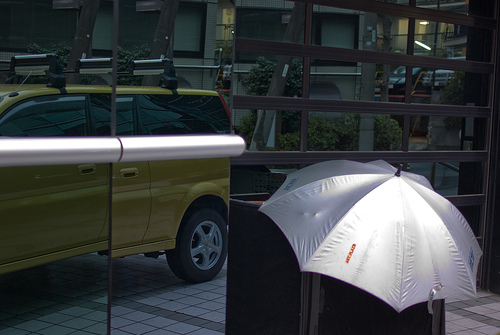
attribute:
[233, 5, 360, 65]
window — rectangular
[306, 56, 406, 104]
window — rectangular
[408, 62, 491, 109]
window — rectangular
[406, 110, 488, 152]
window — rectangular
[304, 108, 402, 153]
window — rectangular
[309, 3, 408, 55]
window — rectangular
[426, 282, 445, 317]
strap — small, grey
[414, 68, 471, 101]
window — rectangular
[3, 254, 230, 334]
tiles — grey , cement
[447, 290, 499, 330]
tiles — grey , cement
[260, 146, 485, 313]
umbrella — white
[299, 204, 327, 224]
bump — small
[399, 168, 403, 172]
black — small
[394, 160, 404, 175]
cap — small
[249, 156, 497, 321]
umbrella — white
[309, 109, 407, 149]
window — rectangular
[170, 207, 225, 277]
tire —  large,  black,  vehicle's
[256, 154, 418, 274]
umbrella — opened, white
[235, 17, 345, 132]
tree — small green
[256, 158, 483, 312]
umbrella — white, open, shiny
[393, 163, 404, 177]
top — pointed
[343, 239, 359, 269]
label — red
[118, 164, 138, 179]
handle — small, yellow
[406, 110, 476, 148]
window — rectangular